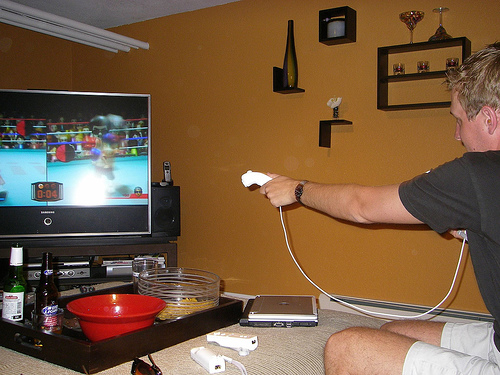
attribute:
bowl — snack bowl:
[120, 259, 218, 324]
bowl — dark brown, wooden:
[116, 252, 248, 309]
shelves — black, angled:
[369, 26, 497, 123]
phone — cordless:
[158, 158, 174, 186]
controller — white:
[188, 343, 248, 373]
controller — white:
[206, 329, 259, 356]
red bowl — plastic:
[52, 285, 147, 335]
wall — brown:
[71, 2, 498, 316]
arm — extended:
[257, 150, 498, 240]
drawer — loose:
[0, 268, 247, 373]